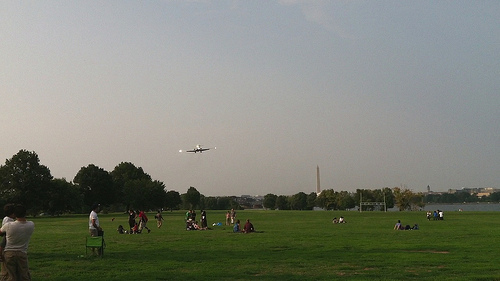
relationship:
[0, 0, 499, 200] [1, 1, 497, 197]
cloud in sky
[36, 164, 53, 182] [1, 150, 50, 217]
leaves on tree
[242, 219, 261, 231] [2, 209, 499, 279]
people sitting on grass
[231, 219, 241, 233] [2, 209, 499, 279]
people sitting on grass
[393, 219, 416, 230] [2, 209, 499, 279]
people sitting on grass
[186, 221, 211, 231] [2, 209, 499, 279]
people sitting on grass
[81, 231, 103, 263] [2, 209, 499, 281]
chair on grass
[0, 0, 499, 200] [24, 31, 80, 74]
cloud in sky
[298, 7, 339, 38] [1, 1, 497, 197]
cloud in sky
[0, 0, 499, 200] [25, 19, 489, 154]
cloud in sky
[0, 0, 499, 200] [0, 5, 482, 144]
cloud in sky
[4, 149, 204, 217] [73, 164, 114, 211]
leaves on tree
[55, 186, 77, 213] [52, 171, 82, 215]
leaves on tree